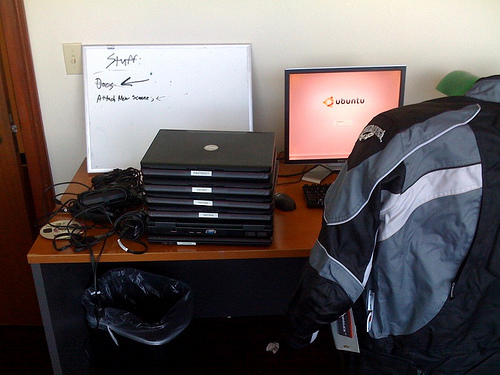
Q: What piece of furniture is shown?
A: Desk.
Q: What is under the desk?
A: Trash can.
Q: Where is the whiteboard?
A: On the desk.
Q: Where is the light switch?
A: Left of the whiteboard.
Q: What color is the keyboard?
A: Black.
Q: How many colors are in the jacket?
A: Three.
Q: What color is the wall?
A: White.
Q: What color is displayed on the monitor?
A: Red.